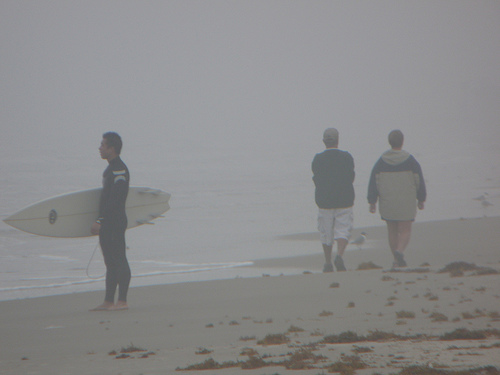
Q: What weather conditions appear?
A: It is foggy.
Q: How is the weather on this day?
A: It is foggy.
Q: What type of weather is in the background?
A: It is foggy.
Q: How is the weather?
A: It is foggy.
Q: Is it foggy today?
A: Yes, it is foggy.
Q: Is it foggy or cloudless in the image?
A: It is foggy.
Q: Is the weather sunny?
A: No, it is foggy.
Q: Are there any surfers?
A: Yes, there is a surfer.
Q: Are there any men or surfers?
A: Yes, there is a surfer.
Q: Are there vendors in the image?
A: No, there are no vendors.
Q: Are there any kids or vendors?
A: No, there are no vendors or kids.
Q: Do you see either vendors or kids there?
A: No, there are no vendors or kids.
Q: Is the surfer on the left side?
A: Yes, the surfer is on the left of the image.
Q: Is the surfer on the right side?
A: No, the surfer is on the left of the image.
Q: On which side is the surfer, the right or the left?
A: The surfer is on the left of the image.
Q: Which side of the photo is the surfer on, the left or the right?
A: The surfer is on the left of the image.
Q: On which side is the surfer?
A: The surfer is on the left of the image.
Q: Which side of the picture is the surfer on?
A: The surfer is on the left of the image.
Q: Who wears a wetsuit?
A: The surfer wears a wetsuit.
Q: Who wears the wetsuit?
A: The surfer wears a wetsuit.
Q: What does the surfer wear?
A: The surfer wears a wetsuit.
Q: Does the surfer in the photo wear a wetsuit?
A: Yes, the surfer wears a wetsuit.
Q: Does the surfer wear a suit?
A: No, the surfer wears a wetsuit.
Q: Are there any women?
A: Yes, there is a woman.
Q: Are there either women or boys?
A: Yes, there is a woman.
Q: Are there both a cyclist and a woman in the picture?
A: No, there is a woman but no cyclists.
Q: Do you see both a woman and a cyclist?
A: No, there is a woman but no cyclists.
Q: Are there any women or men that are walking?
A: Yes, the woman is walking.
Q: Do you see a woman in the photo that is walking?
A: Yes, there is a woman that is walking.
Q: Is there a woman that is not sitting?
A: Yes, there is a woman that is walking.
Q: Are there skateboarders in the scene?
A: No, there are no skateboarders.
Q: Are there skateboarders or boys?
A: No, there are no skateboarders or boys.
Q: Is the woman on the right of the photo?
A: Yes, the woman is on the right of the image.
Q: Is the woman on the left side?
A: No, the woman is on the right of the image.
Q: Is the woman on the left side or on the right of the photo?
A: The woman is on the right of the image.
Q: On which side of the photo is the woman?
A: The woman is on the right of the image.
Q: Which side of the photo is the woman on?
A: The woman is on the right of the image.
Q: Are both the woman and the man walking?
A: Yes, both the woman and the man are walking.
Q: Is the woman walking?
A: Yes, the woman is walking.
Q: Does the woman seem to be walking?
A: Yes, the woman is walking.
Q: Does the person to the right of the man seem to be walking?
A: Yes, the woman is walking.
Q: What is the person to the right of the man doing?
A: The woman is walking.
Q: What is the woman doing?
A: The woman is walking.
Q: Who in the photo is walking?
A: The woman is walking.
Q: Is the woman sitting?
A: No, the woman is walking.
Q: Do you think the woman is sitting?
A: No, the woman is walking.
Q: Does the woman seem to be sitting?
A: No, the woman is walking.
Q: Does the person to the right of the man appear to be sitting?
A: No, the woman is walking.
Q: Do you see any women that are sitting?
A: No, there is a woman but she is walking.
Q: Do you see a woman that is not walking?
A: No, there is a woman but she is walking.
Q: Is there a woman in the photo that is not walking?
A: No, there is a woman but she is walking.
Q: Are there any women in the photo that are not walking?
A: No, there is a woman but she is walking.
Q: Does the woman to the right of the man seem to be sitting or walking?
A: The woman is walking.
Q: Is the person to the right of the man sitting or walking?
A: The woman is walking.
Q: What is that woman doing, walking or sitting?
A: The woman is walking.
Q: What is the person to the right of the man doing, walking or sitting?
A: The woman is walking.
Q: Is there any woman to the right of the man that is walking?
A: Yes, there is a woman to the right of the man.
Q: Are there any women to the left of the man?
A: No, the woman is to the right of the man.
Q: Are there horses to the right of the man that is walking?
A: No, there is a woman to the right of the man.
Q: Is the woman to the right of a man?
A: Yes, the woman is to the right of a man.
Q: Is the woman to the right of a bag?
A: No, the woman is to the right of a man.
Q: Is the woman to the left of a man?
A: No, the woman is to the right of a man.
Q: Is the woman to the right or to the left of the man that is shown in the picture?
A: The woman is to the right of the man.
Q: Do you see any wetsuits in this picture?
A: Yes, there is a wetsuit.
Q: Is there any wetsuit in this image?
A: Yes, there is a wetsuit.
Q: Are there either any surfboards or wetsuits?
A: Yes, there is a wetsuit.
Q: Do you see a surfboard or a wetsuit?
A: Yes, there is a wetsuit.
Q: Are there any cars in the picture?
A: No, there are no cars.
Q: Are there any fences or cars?
A: No, there are no cars or fences.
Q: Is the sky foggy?
A: Yes, the sky is foggy.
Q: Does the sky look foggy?
A: Yes, the sky is foggy.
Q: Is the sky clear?
A: No, the sky is foggy.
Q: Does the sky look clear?
A: No, the sky is foggy.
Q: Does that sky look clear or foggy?
A: The sky is foggy.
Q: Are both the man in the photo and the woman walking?
A: Yes, both the man and the woman are walking.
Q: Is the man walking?
A: Yes, the man is walking.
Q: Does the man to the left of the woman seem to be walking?
A: Yes, the man is walking.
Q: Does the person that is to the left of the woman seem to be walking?
A: Yes, the man is walking.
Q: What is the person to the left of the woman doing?
A: The man is walking.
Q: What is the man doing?
A: The man is walking.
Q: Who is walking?
A: The man is walking.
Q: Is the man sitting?
A: No, the man is walking.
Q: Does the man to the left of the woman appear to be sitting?
A: No, the man is walking.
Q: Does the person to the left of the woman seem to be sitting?
A: No, the man is walking.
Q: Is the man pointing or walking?
A: The man is walking.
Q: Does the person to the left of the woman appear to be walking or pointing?
A: The man is walking.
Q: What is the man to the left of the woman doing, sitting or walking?
A: The man is walking.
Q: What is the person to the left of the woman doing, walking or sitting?
A: The man is walking.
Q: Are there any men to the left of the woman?
A: Yes, there is a man to the left of the woman.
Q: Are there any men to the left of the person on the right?
A: Yes, there is a man to the left of the woman.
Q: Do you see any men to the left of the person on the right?
A: Yes, there is a man to the left of the woman.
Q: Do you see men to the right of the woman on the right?
A: No, the man is to the left of the woman.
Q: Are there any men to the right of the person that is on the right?
A: No, the man is to the left of the woman.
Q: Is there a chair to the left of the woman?
A: No, there is a man to the left of the woman.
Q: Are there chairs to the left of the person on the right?
A: No, there is a man to the left of the woman.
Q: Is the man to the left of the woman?
A: Yes, the man is to the left of the woman.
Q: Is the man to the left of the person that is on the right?
A: Yes, the man is to the left of the woman.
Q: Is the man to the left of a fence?
A: No, the man is to the left of the woman.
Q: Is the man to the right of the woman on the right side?
A: No, the man is to the left of the woman.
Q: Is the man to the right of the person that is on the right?
A: No, the man is to the left of the woman.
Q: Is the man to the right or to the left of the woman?
A: The man is to the left of the woman.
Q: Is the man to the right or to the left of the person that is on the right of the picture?
A: The man is to the left of the woman.